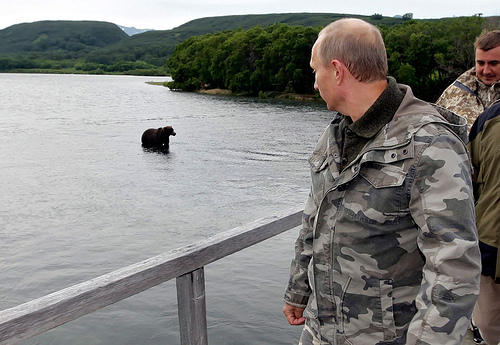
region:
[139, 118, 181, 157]
large bear in water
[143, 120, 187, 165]
large horse in water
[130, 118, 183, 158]
horse soaking wet in water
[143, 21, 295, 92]
large green trees by water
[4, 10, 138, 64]
mountain range of trees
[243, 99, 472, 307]
camouflage jacket on man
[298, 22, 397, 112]
vladmir putin with head turned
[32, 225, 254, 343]
wooden bars to bridge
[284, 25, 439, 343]
definitely vladmir putin here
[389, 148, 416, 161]
silver buttons on jacket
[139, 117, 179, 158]
a bear in the water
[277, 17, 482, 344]
the man is looking at the bear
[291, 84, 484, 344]
the man is wearing a camouflage coat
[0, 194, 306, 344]
the railing is wooden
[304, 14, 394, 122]
the man has gray hair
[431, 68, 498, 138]
the man is wearing a brown coat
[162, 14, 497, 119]
trees by the water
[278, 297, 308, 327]
the man has a hand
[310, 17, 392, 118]
the man is going bald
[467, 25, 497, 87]
the man has brown hair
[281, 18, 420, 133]
the head of a man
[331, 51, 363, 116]
the ear of a man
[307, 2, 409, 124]
the hair of a man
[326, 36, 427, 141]
the neck of a man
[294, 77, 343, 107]
the nose of a man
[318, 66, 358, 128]
the chin of a man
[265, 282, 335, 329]
the hand of a man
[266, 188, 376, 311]
the arm of a man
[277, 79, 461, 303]
a man wearing a jacket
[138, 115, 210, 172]
a bear in the water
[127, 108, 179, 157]
a bear in a water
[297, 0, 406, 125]
head of a person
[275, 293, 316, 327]
hand of a person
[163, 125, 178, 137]
head of a bear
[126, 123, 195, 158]
a big black bear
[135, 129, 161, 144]
body of a bear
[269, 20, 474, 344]
person wearing a camouflage jacket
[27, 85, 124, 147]
a body of water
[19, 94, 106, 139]
a body of clear water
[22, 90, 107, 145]
a very clear body of water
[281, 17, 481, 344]
Man watching bear in water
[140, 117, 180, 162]
Bear is in water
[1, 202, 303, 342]
Hand rails are made of wood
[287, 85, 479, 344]
Man wearing green camouflage jacket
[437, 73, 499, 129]
Man wearing brown camouflage jacket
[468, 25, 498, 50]
Man has brown hair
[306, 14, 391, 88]
Man is balding on top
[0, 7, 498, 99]
Hills in background are green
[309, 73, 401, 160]
Man wearing green shirt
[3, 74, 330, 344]
Water looks dark and murky